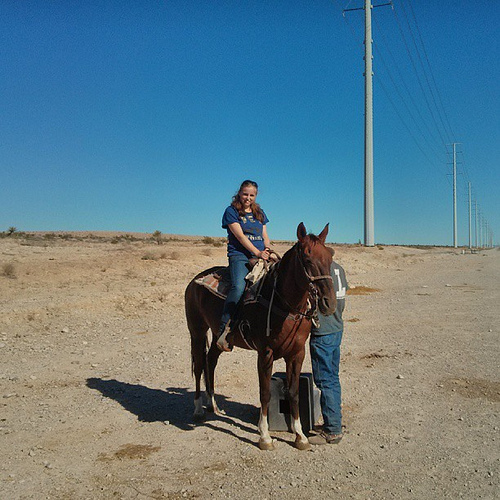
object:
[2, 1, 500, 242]
sky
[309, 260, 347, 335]
t-shirt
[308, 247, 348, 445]
man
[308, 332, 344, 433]
jeans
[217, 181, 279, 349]
woman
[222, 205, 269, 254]
shirt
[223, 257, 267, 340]
jeans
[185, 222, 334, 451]
horse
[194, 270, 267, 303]
blanket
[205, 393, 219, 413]
white stocking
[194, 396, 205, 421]
white stocking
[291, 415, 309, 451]
white feet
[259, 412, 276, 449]
white stocking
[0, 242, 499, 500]
ground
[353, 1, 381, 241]
post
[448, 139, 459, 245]
post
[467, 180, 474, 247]
post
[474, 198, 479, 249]
post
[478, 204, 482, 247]
post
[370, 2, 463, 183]
wires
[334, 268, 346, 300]
number one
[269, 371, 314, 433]
box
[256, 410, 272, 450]
white feet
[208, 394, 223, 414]
white feet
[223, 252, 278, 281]
saddle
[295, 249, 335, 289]
bridle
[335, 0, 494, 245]
power lines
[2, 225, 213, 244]
vegetation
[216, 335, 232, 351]
rider's foot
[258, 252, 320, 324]
reins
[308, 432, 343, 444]
cowboy boots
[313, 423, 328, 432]
cowboy boots